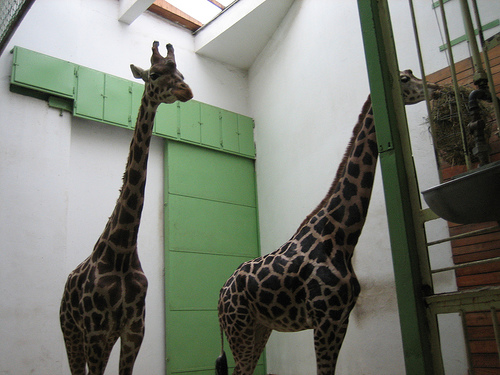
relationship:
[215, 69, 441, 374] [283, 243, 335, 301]
eating giraffe has spots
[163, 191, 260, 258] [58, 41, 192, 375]
green panel behind giraffe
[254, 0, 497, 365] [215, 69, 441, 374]
wall near eating giraffe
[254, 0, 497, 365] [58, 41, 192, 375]
wall near giraffe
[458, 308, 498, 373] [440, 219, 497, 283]
wood paneling on wall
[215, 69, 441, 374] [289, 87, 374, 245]
eating giraffe has mane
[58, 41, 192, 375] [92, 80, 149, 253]
giraffe has mane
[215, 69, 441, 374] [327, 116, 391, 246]
eating giraffe has neck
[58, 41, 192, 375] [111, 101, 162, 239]
giraffe has neck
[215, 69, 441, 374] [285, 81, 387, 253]
eating giraffe has neck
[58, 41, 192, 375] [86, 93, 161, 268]
giraffe has neck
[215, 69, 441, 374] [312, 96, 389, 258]
eating giraffe has neck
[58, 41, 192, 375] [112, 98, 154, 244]
giraffe has neck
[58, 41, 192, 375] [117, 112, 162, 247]
giraffe has neck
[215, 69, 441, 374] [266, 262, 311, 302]
eating giraffe has spots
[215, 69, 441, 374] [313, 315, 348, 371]
eating giraffe has legs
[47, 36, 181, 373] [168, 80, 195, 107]
giraffe has nose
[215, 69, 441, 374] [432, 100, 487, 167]
eating giraffe has hay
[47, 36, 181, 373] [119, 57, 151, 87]
giraffe has ear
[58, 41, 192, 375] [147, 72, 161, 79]
giraffe has eye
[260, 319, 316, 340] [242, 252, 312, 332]
edge of a stomach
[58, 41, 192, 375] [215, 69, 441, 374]
giraffe next to eating giraffe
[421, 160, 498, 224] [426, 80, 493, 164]
basin by hay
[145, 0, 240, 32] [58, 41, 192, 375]
skylight above giraffe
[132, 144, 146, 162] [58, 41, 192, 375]
spot on giraffe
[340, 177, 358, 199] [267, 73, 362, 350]
spot on giraffe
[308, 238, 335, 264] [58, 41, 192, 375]
spot on giraffe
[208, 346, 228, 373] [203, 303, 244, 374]
tuft on tail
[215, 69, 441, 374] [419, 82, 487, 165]
eating giraffe eating hay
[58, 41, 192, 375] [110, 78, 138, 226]
giraffe has mane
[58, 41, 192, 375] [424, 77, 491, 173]
giraffe eating hay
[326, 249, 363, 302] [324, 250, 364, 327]
part of chest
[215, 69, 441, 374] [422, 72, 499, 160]
eating giraffe eating hay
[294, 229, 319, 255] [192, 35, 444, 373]
spot on giraffe